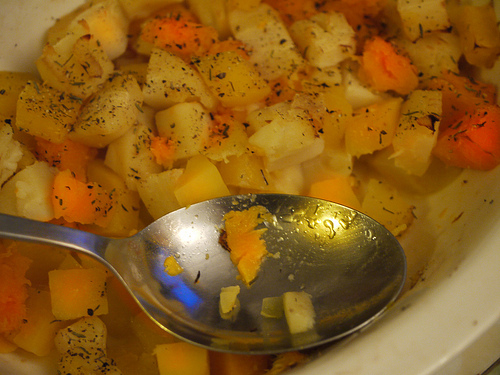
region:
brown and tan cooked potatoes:
[14, 20, 137, 76]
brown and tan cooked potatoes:
[36, 80, 114, 140]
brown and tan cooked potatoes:
[11, 268, 93, 343]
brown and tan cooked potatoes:
[10, 135, 96, 223]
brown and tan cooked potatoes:
[160, 97, 223, 159]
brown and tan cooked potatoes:
[360, 112, 423, 188]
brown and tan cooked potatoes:
[184, 30, 284, 116]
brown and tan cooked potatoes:
[299, 16, 411, 113]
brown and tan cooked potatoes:
[387, 40, 484, 161]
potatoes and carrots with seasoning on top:
[16, 17, 480, 187]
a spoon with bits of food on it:
[113, 193, 398, 340]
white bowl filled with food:
[358, 160, 487, 373]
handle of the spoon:
[2, 199, 129, 297]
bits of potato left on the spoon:
[211, 283, 323, 329]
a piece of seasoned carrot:
[449, 63, 499, 185]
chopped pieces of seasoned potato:
[17, 38, 144, 139]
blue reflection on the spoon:
[138, 240, 213, 315]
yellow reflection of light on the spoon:
[295, 190, 367, 252]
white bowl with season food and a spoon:
[17, 3, 499, 369]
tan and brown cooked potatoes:
[0, 40, 125, 125]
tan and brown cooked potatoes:
[45, 15, 140, 115]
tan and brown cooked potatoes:
[54, 54, 186, 132]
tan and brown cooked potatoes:
[202, 35, 298, 117]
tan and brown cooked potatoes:
[309, 0, 456, 122]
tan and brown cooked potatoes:
[378, 100, 495, 199]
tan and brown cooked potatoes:
[203, 111, 335, 173]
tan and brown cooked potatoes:
[406, 24, 480, 103]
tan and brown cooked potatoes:
[266, 5, 394, 86]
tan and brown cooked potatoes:
[16, 140, 106, 217]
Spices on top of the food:
[162, 63, 228, 100]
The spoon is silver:
[148, 179, 381, 342]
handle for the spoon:
[7, 186, 126, 271]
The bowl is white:
[410, 251, 495, 356]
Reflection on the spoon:
[280, 188, 421, 280]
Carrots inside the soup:
[422, 95, 495, 167]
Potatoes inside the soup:
[68, 48, 173, 163]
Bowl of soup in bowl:
[35, 46, 470, 344]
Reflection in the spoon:
[116, 233, 216, 348]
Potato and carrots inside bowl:
[384, 76, 492, 177]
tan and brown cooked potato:
[0, 91, 90, 151]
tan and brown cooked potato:
[16, 5, 132, 118]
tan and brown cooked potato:
[100, 97, 206, 173]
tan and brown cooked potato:
[17, 274, 118, 356]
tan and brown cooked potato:
[24, 112, 153, 185]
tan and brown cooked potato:
[330, 137, 452, 188]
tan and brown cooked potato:
[214, 8, 354, 81]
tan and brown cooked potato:
[256, 72, 337, 147]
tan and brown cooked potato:
[329, 8, 416, 71]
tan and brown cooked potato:
[349, 83, 469, 148]